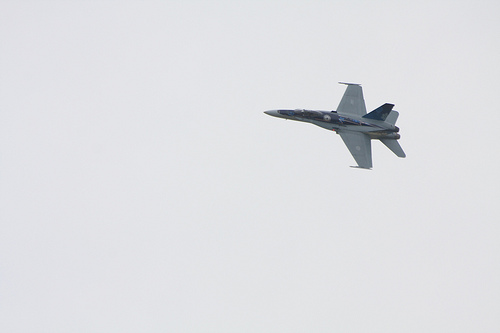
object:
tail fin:
[362, 102, 394, 121]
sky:
[0, 1, 498, 331]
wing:
[334, 127, 379, 170]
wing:
[333, 79, 368, 115]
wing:
[368, 97, 401, 129]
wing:
[382, 139, 406, 159]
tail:
[362, 103, 406, 159]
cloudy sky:
[0, 1, 500, 330]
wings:
[339, 127, 374, 168]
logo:
[349, 100, 356, 107]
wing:
[376, 136, 409, 159]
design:
[329, 110, 339, 123]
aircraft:
[259, 78, 409, 170]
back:
[264, 103, 401, 133]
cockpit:
[282, 110, 298, 116]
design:
[355, 143, 362, 152]